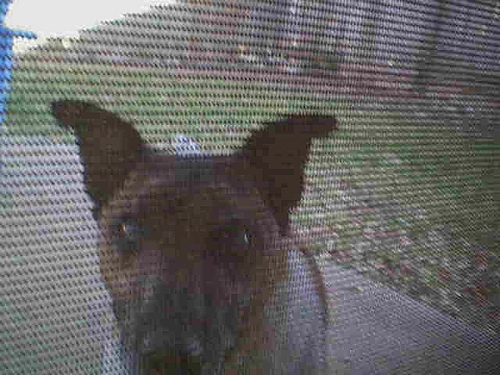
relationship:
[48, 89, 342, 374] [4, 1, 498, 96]
dog standing behind fence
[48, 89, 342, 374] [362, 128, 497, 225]
dog standing by grass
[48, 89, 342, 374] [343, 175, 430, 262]
dog standing by grass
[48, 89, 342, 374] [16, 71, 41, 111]
dog standing by grass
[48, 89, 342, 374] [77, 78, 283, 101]
dog standing by grass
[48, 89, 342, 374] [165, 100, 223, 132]
dog standing by grass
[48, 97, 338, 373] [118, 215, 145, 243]
dog has eye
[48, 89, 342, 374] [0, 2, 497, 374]
dog standing behind a fence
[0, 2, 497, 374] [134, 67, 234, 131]
fence by grass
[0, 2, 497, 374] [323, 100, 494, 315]
fence by grass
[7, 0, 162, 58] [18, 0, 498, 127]
light on fence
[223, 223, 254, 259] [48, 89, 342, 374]
eye belonging to dog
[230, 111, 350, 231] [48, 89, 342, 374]
ear belonging to dog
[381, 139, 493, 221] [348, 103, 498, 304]
leaves on ground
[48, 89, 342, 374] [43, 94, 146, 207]
dog has ear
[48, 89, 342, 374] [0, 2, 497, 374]
dog standing behind fence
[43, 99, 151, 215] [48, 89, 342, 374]
ear on dog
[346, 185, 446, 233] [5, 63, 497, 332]
leaves on grass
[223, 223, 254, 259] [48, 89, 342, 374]
eye on dog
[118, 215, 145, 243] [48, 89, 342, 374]
eye on dog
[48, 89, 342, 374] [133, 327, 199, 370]
dog has nose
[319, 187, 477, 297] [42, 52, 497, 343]
leaves on ground